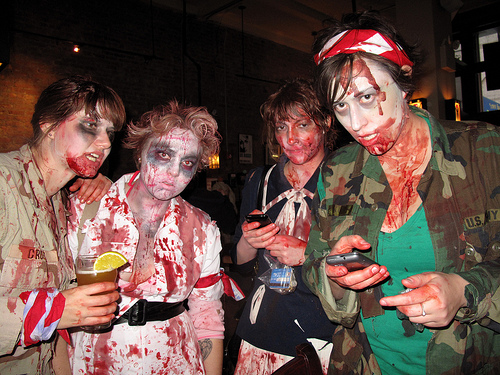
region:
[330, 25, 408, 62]
Person wearing red and white band on head.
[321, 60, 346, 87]
Person has dark hair.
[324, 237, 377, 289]
Person holding gray cell phone.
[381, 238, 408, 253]
Person wearing green shirt.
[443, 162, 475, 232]
Camo shirt over green shirt.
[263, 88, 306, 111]
Person has brown hair.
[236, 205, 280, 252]
Person holding black cell phone.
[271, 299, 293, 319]
Person wearing black shirt.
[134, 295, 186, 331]
Person wearing black belt.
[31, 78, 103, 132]
Person has brown hair.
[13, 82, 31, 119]
this is the wall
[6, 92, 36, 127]
the wall is clean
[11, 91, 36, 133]
the wall is brown in color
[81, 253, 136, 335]
this is a cup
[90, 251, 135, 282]
slice of an orange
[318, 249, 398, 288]
this is a mobile phone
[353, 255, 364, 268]
the phone is grey in color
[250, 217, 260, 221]
the phone is black in color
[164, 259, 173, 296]
these are red stains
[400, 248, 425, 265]
the cloth is green in color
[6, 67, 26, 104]
this is the wall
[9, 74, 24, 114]
the wall is clean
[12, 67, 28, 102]
the wall is brown in color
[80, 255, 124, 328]
this is a cup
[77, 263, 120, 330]
the cup is made of glass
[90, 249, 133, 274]
slice of an orange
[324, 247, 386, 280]
this is a mobile phone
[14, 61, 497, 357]
these are some women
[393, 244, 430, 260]
the vest is green in color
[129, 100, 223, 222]
this is a lady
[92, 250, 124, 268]
this is an orange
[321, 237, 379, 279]
this is a cell phone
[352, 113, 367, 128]
this is the nose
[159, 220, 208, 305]
the clothe is bloody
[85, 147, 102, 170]
the mouth is open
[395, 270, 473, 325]
these are the fingers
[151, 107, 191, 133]
this is the hair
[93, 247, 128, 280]
slice of lemon on edge of cup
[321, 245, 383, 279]
grey cell phone in hand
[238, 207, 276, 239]
black cell phone in hand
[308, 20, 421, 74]
red and white head band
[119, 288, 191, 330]
black belt with buckle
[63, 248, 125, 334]
cup of light brown beverage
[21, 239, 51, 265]
letters in black print on front of tan shirt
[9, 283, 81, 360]
red and white scarf tied around wrist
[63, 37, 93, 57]
one ceiling light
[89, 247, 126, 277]
Orange on a glass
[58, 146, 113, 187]
Fake blood on face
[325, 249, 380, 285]
Phone in person's hand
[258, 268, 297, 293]
Card in a plastic bag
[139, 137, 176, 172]
Dark makeup around eyes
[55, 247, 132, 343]
Glass of drink with an orange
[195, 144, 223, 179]
Light in the background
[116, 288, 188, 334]
Black belt on outfit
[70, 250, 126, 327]
A woman is holding a drink.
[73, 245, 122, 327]
A woman is holding a drink.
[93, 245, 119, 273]
The yellow lemon is on the glass.